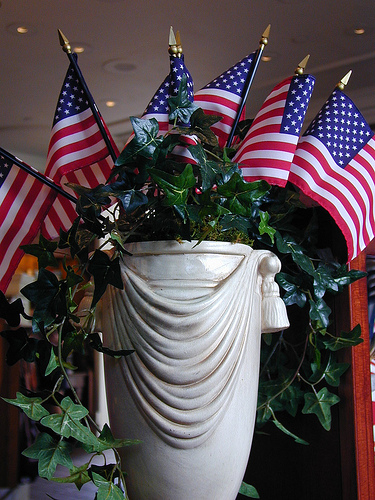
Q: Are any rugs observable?
A: No, there are no rugs.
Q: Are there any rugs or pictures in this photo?
A: No, there are no rugs or pictures.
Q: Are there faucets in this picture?
A: No, there are no faucets.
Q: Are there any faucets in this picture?
A: No, there are no faucets.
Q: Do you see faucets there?
A: No, there are no faucets.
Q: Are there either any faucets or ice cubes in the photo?
A: No, there are no faucets or ice cubes.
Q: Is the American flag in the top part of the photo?
A: Yes, the American flag is in the top of the image.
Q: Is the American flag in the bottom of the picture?
A: No, the American flag is in the top of the image.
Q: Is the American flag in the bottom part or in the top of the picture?
A: The American flag is in the top of the image.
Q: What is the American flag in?
A: The American flag is in the vase.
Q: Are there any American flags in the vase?
A: Yes, there is an American flag in the vase.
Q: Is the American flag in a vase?
A: Yes, the American flag is in a vase.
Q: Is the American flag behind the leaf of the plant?
A: Yes, the American flag is behind the leaf.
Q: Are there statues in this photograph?
A: No, there are no statues.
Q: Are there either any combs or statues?
A: No, there are no statues or combs.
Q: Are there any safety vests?
A: No, there are no safety vests.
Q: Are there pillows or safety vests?
A: No, there are no safety vests or pillows.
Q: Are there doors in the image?
A: Yes, there is a door.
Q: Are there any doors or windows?
A: Yes, there is a door.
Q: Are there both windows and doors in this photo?
A: No, there is a door but no windows.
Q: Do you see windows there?
A: No, there are no windows.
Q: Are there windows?
A: No, there are no windows.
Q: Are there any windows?
A: No, there are no windows.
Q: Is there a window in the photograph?
A: No, there are no windows.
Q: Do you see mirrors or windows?
A: No, there are no windows or mirrors.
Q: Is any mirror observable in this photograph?
A: No, there are no mirrors.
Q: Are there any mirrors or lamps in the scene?
A: No, there are no mirrors or lamps.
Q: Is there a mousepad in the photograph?
A: No, there are no mouse pads.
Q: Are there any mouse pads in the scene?
A: No, there are no mouse pads.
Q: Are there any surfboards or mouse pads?
A: No, there are no mouse pads or surfboards.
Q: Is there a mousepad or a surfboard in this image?
A: No, there are no mouse pads or surfboards.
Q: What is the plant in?
A: The plant is in the vase.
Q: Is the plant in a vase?
A: Yes, the plant is in a vase.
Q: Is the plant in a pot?
A: No, the plant is in a vase.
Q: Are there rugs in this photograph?
A: No, there are no rugs.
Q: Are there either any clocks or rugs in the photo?
A: No, there are no rugs or clocks.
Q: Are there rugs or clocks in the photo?
A: No, there are no rugs or clocks.